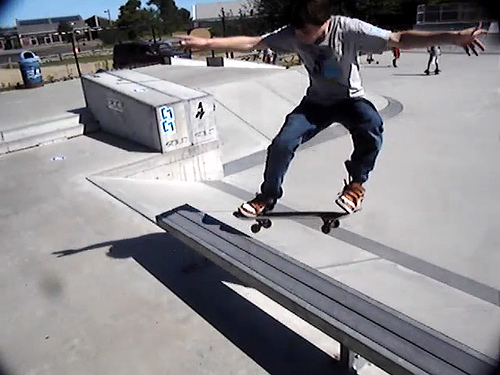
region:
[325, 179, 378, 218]
brown and white sneakers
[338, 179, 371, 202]
laces in brown sneakers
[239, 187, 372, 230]
skate board on ramp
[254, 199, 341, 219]
gray color on skate board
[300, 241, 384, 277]
deep line in the ramp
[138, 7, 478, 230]
skater balancing on the ramp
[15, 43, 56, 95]
large blue trash can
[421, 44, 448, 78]
person skating on the ground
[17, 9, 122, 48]
large house on the side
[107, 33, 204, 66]
black suv in parking lot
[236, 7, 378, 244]
boy on a skate board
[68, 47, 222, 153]
shipping container in a skate park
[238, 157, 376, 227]
boy wearing brown shoes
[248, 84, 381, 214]
boy wearing blue jeans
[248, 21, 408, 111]
boy wearing a grey shirt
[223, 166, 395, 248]
boy doing a trick on a skate board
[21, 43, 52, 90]
garbage cans on a skate board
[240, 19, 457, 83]
people in the skate park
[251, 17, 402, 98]
person in a gray shirt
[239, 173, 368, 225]
guy wearing brown shoes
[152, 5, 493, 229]
person wearing pair of sneakers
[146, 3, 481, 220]
person wearing blue jeans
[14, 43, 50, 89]
a garbage disposal on street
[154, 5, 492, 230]
person on his skateboard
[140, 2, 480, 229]
person wearing a gray shirt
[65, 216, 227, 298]
shadows of a person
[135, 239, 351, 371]
shadows of a ramp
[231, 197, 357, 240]
skateboard in mid air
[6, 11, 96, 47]
a house on the street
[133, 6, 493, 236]
person jumping with his skateboard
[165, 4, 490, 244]
person jumping with skateboard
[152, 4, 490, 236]
person wearing a pair of sneakers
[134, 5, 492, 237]
person wear blue jeans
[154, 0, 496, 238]
person spreading arms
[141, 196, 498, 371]
a skateboard skating ramp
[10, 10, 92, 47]
a building on a street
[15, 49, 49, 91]
garbage can on street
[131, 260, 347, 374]
shadows reflected from ramp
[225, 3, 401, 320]
the boy is skateboarding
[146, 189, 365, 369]
the bench is gray